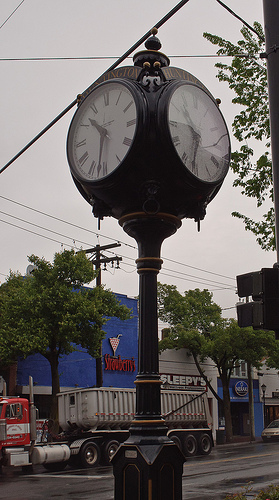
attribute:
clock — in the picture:
[66, 36, 248, 224]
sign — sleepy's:
[160, 369, 209, 390]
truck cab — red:
[1, 391, 34, 473]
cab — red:
[0, 397, 29, 446]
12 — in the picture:
[99, 88, 111, 106]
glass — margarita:
[108, 336, 120, 357]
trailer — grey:
[53, 386, 218, 429]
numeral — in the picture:
[73, 139, 88, 147]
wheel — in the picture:
[79, 439, 100, 468]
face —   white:
[97, 124, 215, 179]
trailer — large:
[49, 386, 220, 435]